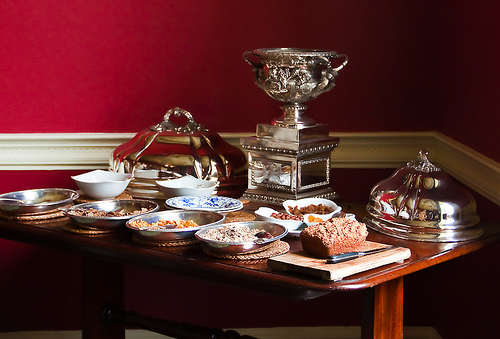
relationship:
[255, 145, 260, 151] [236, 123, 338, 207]
dot on base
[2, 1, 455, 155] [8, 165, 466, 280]
wall behind table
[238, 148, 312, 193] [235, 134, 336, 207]
dot on base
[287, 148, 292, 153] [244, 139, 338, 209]
dot on base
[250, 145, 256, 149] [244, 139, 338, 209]
dot on base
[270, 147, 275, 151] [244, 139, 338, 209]
dot on base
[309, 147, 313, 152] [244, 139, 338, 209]
dot on base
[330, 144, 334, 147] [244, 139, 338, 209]
dot on base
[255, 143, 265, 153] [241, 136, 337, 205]
dot on base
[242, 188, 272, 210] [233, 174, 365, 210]
silver dot on base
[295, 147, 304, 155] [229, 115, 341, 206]
dot on base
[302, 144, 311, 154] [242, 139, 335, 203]
dot on base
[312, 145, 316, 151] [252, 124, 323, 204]
dot on base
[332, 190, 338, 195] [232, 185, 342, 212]
dot on base